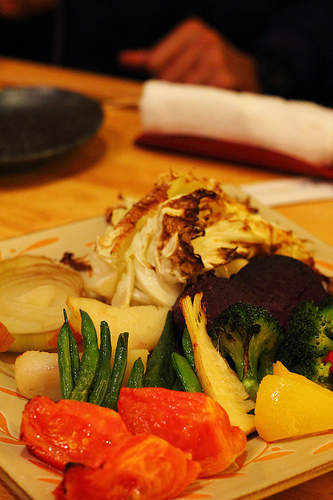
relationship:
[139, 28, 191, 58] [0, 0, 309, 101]
hand of man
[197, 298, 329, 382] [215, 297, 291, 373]
stalks of broccoli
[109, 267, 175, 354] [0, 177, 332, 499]
pineapple on dish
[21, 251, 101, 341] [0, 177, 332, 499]
onions on dish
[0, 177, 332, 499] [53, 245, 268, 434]
dish of vegetables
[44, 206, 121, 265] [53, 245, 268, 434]
dish has vegetables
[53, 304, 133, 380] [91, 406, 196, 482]
beans by tomatoes